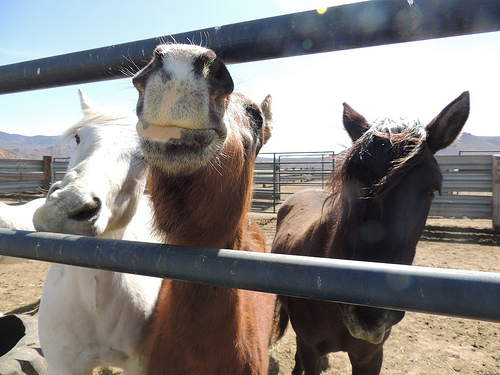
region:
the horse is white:
[26, 126, 150, 317]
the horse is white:
[11, 63, 228, 370]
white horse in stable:
[1, 81, 167, 373]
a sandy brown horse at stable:
[116, 31, 277, 373]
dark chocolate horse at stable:
[269, 86, 473, 374]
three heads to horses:
[28, 33, 474, 345]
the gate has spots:
[1, 232, 494, 317]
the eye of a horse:
[238, 96, 271, 135]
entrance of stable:
[271, 142, 337, 214]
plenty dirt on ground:
[436, 240, 487, 265]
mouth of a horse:
[132, 108, 225, 168]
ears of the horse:
[339, 84, 474, 155]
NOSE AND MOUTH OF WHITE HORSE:
[30, 180, 124, 237]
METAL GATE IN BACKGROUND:
[271, 155, 348, 213]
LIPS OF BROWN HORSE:
[134, 108, 226, 150]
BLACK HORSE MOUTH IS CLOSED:
[344, 308, 404, 345]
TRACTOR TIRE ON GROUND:
[2, 308, 47, 373]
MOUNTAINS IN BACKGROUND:
[0, 127, 72, 153]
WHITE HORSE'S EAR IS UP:
[76, 88, 102, 113]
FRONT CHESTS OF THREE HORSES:
[52, 267, 437, 373]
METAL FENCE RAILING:
[4, 225, 499, 322]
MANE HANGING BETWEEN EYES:
[369, 120, 424, 202]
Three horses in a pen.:
[12, 45, 487, 372]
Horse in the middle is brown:
[106, 24, 285, 366]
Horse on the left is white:
[23, 88, 178, 365]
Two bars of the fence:
[13, 4, 495, 324]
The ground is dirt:
[0, 215, 495, 365]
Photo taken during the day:
[11, 8, 494, 361]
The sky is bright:
[11, 15, 487, 145]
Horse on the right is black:
[285, 82, 472, 367]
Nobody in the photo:
[20, 17, 492, 362]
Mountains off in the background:
[0, 116, 492, 176]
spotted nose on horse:
[127, 40, 241, 179]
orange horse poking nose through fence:
[126, 36, 275, 374]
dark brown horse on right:
[270, 87, 481, 374]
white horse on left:
[2, 87, 163, 372]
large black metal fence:
[2, 1, 498, 323]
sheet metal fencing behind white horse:
[0, 151, 98, 205]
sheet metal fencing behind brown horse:
[427, 148, 497, 223]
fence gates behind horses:
[258, 144, 347, 224]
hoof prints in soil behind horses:
[401, 299, 495, 372]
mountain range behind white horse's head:
[1, 120, 82, 162]